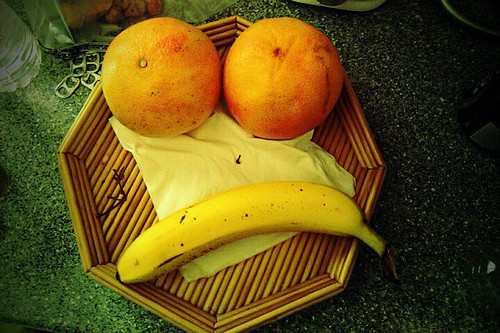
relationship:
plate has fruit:
[161, 284, 318, 328] [105, 17, 391, 281]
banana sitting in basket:
[102, 181, 404, 296] [58, 15, 393, 332]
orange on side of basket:
[222, 14, 347, 138] [58, 15, 393, 332]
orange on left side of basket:
[119, 28, 199, 128] [62, 123, 104, 278]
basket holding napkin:
[75, 17, 380, 318] [101, 92, 357, 268]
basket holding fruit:
[75, 17, 380, 318] [95, 5, 380, 282]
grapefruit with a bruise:
[223, 15, 343, 143] [315, 55, 331, 111]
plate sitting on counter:
[55, 15, 383, 333] [2, 3, 497, 328]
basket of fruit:
[40, 15, 417, 310] [75, 8, 380, 148]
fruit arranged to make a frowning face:
[102, 14, 345, 140] [65, 11, 403, 330]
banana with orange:
[115, 180, 381, 284] [100, 17, 347, 139]